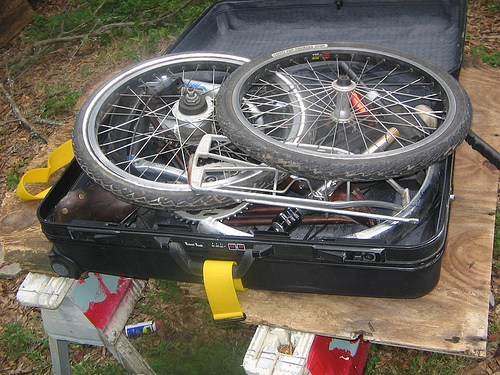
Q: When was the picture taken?
A: Daytime.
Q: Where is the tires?
A: In the case.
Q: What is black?
A: Wheels.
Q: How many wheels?
A: Two.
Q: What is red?
A: Paint.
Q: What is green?
A: Grass.